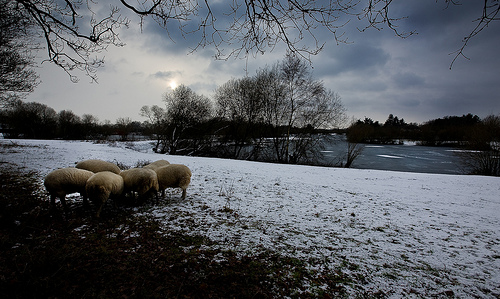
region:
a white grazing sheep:
[41, 166, 87, 200]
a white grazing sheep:
[85, 171, 121, 203]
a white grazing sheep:
[118, 166, 161, 202]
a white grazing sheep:
[149, 162, 191, 196]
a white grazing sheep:
[140, 156, 165, 172]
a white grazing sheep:
[73, 156, 120, 176]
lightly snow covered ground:
[17, 136, 495, 291]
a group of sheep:
[45, 154, 189, 220]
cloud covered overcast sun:
[160, 75, 176, 87]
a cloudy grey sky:
[8, 1, 493, 114]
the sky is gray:
[333, 42, 453, 97]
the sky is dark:
[356, 57, 443, 92]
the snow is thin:
[275, 189, 375, 294]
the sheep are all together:
[26, 148, 209, 218]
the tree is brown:
[208, 62, 351, 163]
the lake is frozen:
[381, 139, 438, 165]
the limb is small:
[46, 10, 116, 77]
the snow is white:
[353, 178, 425, 228]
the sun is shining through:
[159, 58, 199, 98]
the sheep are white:
[49, 159, 210, 206]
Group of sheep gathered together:
[33, 132, 220, 227]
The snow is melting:
[197, 179, 265, 296]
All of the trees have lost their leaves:
[215, 35, 364, 193]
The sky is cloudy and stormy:
[350, 25, 474, 150]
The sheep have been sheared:
[54, 117, 216, 254]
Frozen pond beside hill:
[365, 135, 459, 185]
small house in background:
[389, 120, 429, 158]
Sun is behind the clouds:
[150, 64, 193, 109]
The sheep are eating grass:
[47, 133, 230, 260]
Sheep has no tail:
[121, 162, 171, 204]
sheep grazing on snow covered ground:
[89, 169, 119, 199]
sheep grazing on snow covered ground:
[42, 161, 84, 196]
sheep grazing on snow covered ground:
[124, 166, 164, 198]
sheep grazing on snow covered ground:
[156, 161, 196, 203]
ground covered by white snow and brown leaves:
[167, 207, 260, 269]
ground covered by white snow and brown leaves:
[224, 231, 311, 288]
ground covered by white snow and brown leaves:
[4, 156, 34, 185]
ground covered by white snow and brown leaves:
[268, 188, 366, 257]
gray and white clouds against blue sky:
[342, 54, 440, 104]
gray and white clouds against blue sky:
[120, 63, 177, 89]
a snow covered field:
[279, 190, 333, 279]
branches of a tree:
[267, 67, 310, 111]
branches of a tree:
[36, 8, 113, 82]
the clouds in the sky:
[345, 40, 400, 90]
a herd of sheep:
[43, 147, 193, 220]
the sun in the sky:
[162, 75, 186, 95]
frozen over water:
[379, 144, 403, 166]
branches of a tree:
[168, 89, 203, 123]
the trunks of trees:
[271, 140, 291, 164]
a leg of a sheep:
[176, 187, 190, 203]